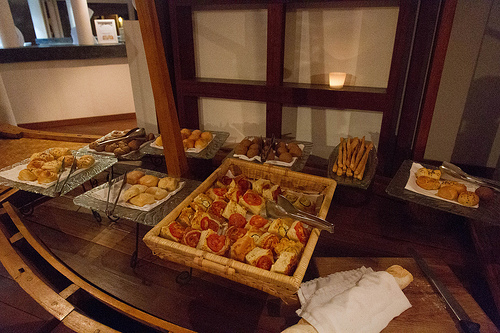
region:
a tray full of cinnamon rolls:
[161, 157, 308, 291]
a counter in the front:
[4, 39, 139, 121]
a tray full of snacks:
[326, 132, 374, 197]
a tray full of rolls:
[413, 160, 488, 212]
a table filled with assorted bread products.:
[1, 121, 494, 331]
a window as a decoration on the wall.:
[173, 5, 444, 170]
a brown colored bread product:
[233, 127, 298, 167]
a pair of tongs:
[261, 195, 336, 246]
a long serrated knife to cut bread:
[403, 248, 475, 329]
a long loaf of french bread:
[263, 265, 420, 330]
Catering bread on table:
[0, 99, 497, 312]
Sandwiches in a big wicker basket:
[142, 155, 344, 300]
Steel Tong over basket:
[265, 188, 341, 241]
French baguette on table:
[254, 254, 428, 332]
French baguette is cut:
[268, 249, 420, 331]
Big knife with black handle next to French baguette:
[411, 240, 491, 330]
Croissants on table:
[0, 133, 102, 194]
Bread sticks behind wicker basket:
[312, 125, 379, 192]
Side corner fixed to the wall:
[0, 133, 495, 328]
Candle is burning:
[326, 65, 352, 93]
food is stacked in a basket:
[146, 153, 339, 301]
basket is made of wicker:
[143, 155, 336, 298]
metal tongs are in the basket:
[263, 190, 334, 237]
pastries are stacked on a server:
[6, 142, 118, 199]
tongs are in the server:
[105, 168, 130, 224]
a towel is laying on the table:
[298, 266, 411, 329]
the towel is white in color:
[295, 261, 407, 330]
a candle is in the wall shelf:
[328, 71, 347, 88]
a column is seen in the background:
[72, 1, 94, 51]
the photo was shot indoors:
[1, 2, 498, 332]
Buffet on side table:
[2, 103, 494, 331]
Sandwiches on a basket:
[142, 151, 339, 299]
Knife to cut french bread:
[394, 236, 479, 331]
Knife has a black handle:
[408, 239, 480, 331]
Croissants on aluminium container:
[11, 136, 104, 193]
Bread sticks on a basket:
[321, 133, 381, 190]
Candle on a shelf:
[322, 63, 347, 88]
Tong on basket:
[264, 190, 338, 239]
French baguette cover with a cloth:
[261, 256, 416, 331]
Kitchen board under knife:
[311, 251, 493, 331]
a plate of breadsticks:
[329, 130, 376, 185]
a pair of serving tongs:
[262, 192, 337, 236]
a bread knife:
[411, 246, 483, 331]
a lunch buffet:
[0, 117, 498, 328]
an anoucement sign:
[88, 15, 123, 47]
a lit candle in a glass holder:
[325, 67, 349, 90]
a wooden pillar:
[128, 0, 195, 178]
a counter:
[0, 33, 139, 135]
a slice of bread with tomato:
[194, 227, 231, 255]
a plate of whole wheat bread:
[86, 125, 153, 157]